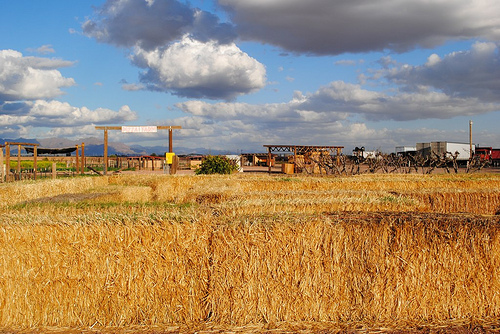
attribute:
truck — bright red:
[464, 131, 499, 174]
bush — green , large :
[188, 151, 243, 182]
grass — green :
[12, 161, 91, 171]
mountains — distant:
[77, 137, 135, 155]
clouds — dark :
[95, 16, 270, 95]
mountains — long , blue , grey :
[22, 143, 277, 171]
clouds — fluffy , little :
[79, 1, 271, 108]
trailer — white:
[409, 130, 488, 157]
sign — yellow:
[164, 151, 174, 167]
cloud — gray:
[440, 67, 488, 119]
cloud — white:
[128, 35, 266, 95]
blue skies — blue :
[0, 2, 498, 149]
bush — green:
[194, 152, 245, 184]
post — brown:
[263, 154, 273, 167]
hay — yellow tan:
[2, 210, 213, 330]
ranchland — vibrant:
[111, 170, 435, 262]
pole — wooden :
[102, 128, 107, 173]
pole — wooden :
[75, 142, 80, 171]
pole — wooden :
[79, 142, 85, 170]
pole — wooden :
[266, 147, 270, 174]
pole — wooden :
[167, 131, 173, 153]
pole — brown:
[166, 118, 181, 160]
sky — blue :
[0, 2, 497, 146]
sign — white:
[106, 111, 163, 139]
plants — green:
[4, 140, 196, 210]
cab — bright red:
[462, 136, 498, 161]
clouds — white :
[1, 37, 441, 147]